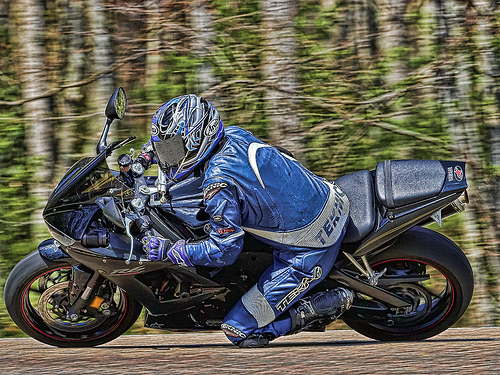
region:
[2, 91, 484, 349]
A motorbike in the photo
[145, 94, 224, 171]
A helmet in the photo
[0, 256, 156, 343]
Wheel of a motorbike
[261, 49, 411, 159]
Trees at the back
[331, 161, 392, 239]
Seat of a motorbike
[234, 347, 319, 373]
Road in the photo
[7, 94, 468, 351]
A person riding a bike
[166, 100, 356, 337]
A man with a motorbike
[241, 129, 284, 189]
Logo on the jacket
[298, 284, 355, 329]
Shoes in the photo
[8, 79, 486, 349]
biker on motorized bike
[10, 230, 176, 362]
front tire on bike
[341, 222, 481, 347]
rear tire on bike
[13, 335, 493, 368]
ground biker rides on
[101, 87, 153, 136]
mirror on the bike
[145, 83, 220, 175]
helmet on biker's head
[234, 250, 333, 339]
pants on the biker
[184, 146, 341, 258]
jacket on the biker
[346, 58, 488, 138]
branches on a tree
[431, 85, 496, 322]
trunk of a tree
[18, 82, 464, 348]
the person on the motorcycle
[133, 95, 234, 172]
the person wearing the helmet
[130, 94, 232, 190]
the helmet is blue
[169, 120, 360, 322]
the person wearing the leather suit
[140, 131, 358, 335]
the suit is blue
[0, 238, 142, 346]
the front wheel of the motorcycle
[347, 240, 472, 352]
the rear wheel of the motorcycle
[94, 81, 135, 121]
the side view mirror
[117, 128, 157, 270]
the handlebars of the motorcycle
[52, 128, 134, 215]
the windshield of the motorcycle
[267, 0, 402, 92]
a bunch of thin green trees.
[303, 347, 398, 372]
a dark grey side walk.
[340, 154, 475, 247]
a dark blue seat on the back of the motorcycle.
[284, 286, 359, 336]
a man is wearing a pair of black boots.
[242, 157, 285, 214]
a man is wearing a blue jacket.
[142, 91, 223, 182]
a man is wearing a blue and black helmet.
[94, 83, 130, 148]
a small black mirror.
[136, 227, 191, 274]
a man is wearing blue gloves.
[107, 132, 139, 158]
a small black break.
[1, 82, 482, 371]
a man is riding a motorcycle .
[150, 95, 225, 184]
A blue and black helmet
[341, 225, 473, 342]
A rear tire on a motorcycle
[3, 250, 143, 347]
A front tire on a motorcycle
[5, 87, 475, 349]
A person on a motorcycle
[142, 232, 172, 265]
A blue glove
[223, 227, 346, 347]
A pair of blue pants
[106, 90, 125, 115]
A mirror on a motorcycle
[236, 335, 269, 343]
A black knee pad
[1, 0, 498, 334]
A blur background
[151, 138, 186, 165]
A reflective front of a helmet